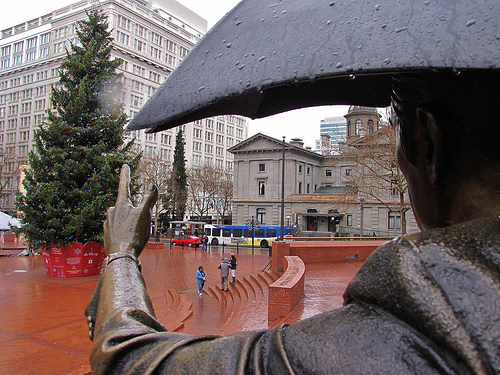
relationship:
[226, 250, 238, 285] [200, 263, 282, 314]
woman standing stairs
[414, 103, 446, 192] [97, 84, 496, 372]
ear on a statue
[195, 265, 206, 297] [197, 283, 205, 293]
woman wears pants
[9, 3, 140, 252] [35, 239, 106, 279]
tree on tree base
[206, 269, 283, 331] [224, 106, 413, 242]
stairs outside building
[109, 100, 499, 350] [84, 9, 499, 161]
bronze statue under umbrella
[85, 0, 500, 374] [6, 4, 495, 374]
bronze statue on photo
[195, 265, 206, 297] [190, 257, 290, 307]
woman standing on stairs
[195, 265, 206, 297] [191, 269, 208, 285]
woman wearing jacket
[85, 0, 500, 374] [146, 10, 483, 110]
bronze statue holding umbrella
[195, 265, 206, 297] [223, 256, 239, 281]
woman wearing coat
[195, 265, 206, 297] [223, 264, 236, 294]
woman wearing pants